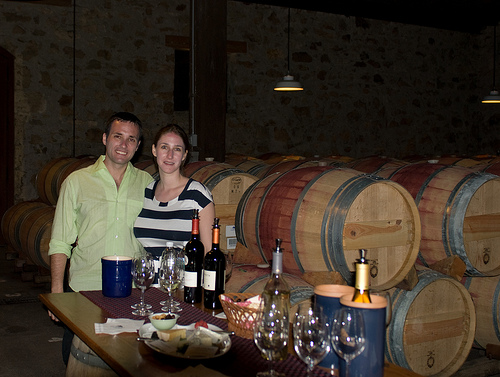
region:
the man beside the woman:
[60, 106, 207, 241]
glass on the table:
[127, 246, 159, 314]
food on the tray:
[136, 302, 224, 362]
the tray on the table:
[127, 315, 232, 358]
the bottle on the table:
[173, 206, 211, 301]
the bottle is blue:
[184, 207, 194, 300]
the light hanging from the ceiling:
[265, 11, 321, 100]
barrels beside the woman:
[192, 131, 498, 348]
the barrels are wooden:
[206, 142, 488, 339]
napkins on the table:
[88, 317, 138, 341]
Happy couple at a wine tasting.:
[35, 100, 215, 289]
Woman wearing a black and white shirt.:
[131, 118, 214, 263]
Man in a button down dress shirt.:
[50, 100, 150, 302]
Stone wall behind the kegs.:
[310, 28, 445, 141]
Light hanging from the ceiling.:
[265, 35, 320, 107]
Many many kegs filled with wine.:
[221, 131, 491, 256]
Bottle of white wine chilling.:
[320, 243, 392, 371]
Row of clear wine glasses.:
[244, 295, 365, 370]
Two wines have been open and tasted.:
[177, 198, 230, 305]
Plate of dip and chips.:
[137, 286, 228, 370]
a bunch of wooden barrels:
[5, 155, 498, 374]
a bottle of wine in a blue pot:
[351, 247, 373, 301]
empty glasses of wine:
[251, 299, 365, 374]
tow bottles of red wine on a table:
[184, 211, 224, 308]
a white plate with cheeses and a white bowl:
[141, 310, 231, 362]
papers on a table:
[93, 315, 143, 335]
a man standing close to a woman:
[48, 113, 215, 324]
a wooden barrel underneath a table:
[64, 332, 112, 374]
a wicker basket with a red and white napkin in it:
[219, 291, 264, 338]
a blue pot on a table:
[100, 253, 132, 296]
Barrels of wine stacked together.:
[263, 161, 495, 268]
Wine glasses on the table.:
[135, 243, 185, 307]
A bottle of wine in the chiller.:
[349, 240, 397, 375]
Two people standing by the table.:
[62, 105, 207, 287]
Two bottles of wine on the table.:
[183, 201, 228, 308]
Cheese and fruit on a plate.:
[143, 308, 213, 355]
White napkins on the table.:
[101, 310, 133, 341]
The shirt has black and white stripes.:
[128, 194, 211, 249]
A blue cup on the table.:
[98, 250, 145, 287]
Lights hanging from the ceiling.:
[258, 75, 498, 116]